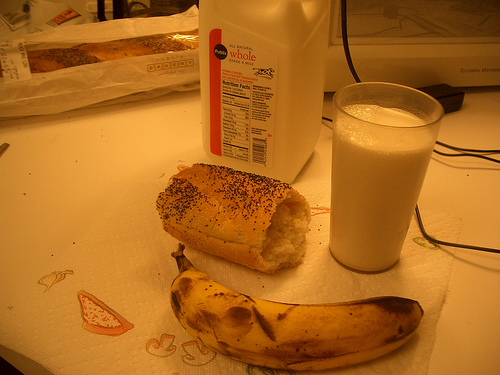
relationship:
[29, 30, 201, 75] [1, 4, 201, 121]
bread in bag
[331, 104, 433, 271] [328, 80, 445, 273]
milk in glass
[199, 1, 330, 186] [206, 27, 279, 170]
container has label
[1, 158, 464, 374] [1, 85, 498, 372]
tissue on table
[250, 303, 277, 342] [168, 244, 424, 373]
bruise on banana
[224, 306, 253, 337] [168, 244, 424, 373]
bruise on banana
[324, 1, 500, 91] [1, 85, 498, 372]
microwave on table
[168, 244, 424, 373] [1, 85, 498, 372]
banana on table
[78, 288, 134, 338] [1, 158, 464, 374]
picture on tissue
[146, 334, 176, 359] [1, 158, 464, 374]
picture on tissue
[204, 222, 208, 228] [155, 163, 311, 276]
seed on bread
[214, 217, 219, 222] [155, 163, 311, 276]
seed on bread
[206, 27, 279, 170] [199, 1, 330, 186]
label on container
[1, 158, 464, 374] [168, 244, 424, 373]
tissue under banana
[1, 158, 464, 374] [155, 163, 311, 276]
tissue under bread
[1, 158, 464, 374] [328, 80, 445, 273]
tissue under glass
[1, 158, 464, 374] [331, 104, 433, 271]
tissue under milk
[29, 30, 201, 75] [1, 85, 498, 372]
bread on table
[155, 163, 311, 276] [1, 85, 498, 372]
bread on table